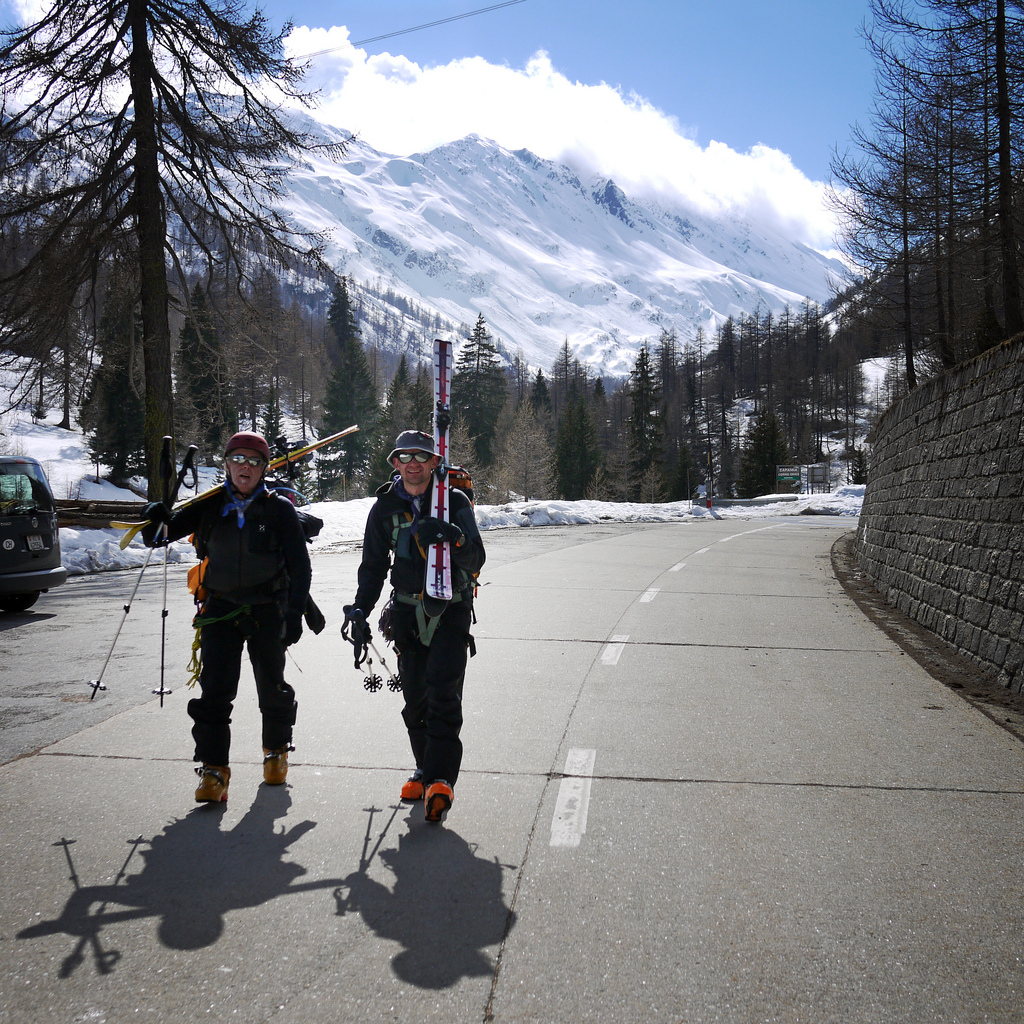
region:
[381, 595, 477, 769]
man wearing black pants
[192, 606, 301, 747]
man wearing black pants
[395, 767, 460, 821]
Man wearing orange boots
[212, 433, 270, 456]
man wearing a orange helmet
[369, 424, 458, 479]
man wearing a grey hat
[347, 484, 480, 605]
man wearing a grey sweater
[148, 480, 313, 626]
man wearing a grey sweater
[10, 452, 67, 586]
car in the parking lot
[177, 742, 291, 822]
Ski boots on a person.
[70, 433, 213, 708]
Ski poles carried by a man.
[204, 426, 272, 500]
Hat on a man.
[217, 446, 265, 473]
Sunglasses on a man.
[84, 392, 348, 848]
Man carrying yellow skis.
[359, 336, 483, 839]
Man carrying red and white skis.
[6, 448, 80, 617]
Car in a parking lot.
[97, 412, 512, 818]
Two men walking on a road.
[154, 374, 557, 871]
Two men carrying skis.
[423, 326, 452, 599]
skis in a man's arms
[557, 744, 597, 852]
a white stripe on the street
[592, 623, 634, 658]
a white stripe on the street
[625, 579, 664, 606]
a white stripe on the street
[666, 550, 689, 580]
a white stripe on the street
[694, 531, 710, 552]
a white stripe on the street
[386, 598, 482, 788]
man wearing black pants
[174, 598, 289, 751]
man wearing black pants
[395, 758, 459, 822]
man wearing orange boots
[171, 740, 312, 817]
man wearing yellow boots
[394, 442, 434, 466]
man wearing silver sunglasses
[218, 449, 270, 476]
man wearing silver sunglasses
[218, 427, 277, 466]
man wearing a red helmet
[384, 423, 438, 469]
man wearing a gray hat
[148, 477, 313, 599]
man wearing a black shirt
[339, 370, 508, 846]
peson carrying skis on road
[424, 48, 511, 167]
white clouds in blue sky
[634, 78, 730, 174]
white clouds in blue sky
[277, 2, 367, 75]
white clouds in blue sky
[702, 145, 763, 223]
white clouds in blue sky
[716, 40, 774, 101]
white clouds in blue sky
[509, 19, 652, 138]
white clouds in blue sky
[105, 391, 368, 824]
man carrying skis